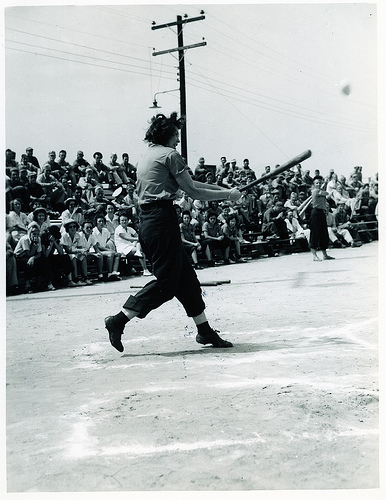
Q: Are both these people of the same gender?
A: Yes, all the people are female.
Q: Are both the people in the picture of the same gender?
A: Yes, all the people are female.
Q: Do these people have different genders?
A: No, all the people are female.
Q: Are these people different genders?
A: No, all the people are female.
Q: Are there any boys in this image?
A: No, there are no boys.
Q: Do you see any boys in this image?
A: No, there are no boys.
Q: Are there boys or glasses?
A: No, there are no boys or glasses.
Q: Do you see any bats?
A: Yes, there is a bat.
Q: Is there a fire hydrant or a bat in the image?
A: Yes, there is a bat.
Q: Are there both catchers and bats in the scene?
A: No, there is a bat but no catchers.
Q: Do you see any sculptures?
A: No, there are no sculptures.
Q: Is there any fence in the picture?
A: No, there are no fences.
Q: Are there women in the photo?
A: Yes, there is a woman.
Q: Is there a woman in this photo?
A: Yes, there is a woman.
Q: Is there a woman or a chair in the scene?
A: Yes, there is a woman.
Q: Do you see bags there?
A: No, there are no bags.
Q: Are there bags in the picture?
A: No, there are no bags.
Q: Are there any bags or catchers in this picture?
A: No, there are no bags or catchers.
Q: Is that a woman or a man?
A: That is a woman.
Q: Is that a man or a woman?
A: That is a woman.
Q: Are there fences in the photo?
A: No, there are no fences.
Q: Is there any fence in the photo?
A: No, there are no fences.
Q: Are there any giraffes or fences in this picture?
A: No, there are no fences or giraffes.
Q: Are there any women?
A: Yes, there is a woman.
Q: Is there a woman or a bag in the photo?
A: Yes, there is a woman.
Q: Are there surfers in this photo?
A: No, there are no surfers.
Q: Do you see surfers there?
A: No, there are no surfers.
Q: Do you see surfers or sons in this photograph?
A: No, there are no surfers or sons.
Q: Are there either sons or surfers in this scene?
A: No, there are no surfers or sons.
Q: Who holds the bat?
A: The woman holds the bat.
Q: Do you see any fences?
A: No, there are no fences.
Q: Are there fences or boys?
A: No, there are no fences or boys.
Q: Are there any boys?
A: No, there are no boys.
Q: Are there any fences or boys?
A: No, there are no boys or fences.